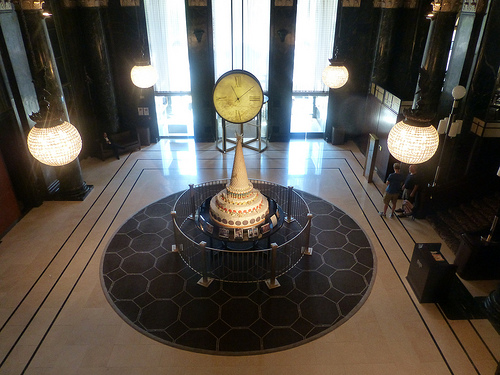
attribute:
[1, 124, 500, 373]
floor — shiny, slippery, beige, reflecting sunlight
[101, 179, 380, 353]
circle — large, black, patterned octagons, patterned squares, brown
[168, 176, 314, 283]
railing — forming circle, metal, circular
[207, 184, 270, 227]
object — round, flat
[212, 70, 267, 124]
clock — lighted, illuminated, large, lit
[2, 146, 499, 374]
triple lines — forming rectangle, black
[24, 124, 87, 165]
lighted globe — glass, made of glass, big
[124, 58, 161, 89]
lighted globe — glass, big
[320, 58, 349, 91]
lighted globe — glass, bulb, big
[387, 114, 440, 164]
lighted globe — glass, big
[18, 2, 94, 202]
column — dark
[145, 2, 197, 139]
window — glass, larger than normal, rectangular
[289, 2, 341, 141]
window — larger than normal, rectangular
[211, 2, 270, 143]
window — larger than normal, large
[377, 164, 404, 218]
person — standing, dark clothed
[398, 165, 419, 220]
person — standing, dark clothed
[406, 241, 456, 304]
reception desk — small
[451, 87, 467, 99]
light — off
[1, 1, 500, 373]
building — large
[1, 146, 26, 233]
door — made of glass